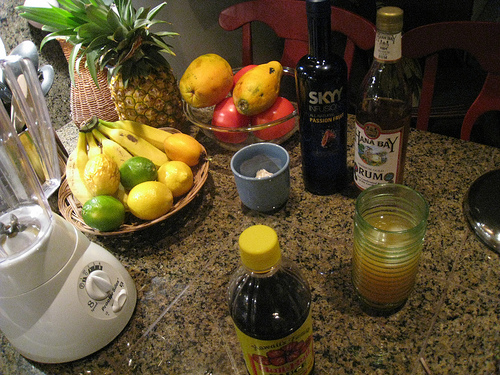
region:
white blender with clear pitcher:
[3, 28, 140, 367]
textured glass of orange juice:
[348, 171, 428, 329]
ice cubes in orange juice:
[368, 204, 419, 263]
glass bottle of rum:
[348, 0, 416, 200]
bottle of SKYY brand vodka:
[291, 2, 353, 197]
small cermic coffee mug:
[220, 140, 298, 220]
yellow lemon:
[118, 170, 179, 225]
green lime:
[78, 192, 128, 238]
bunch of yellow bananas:
[71, 99, 174, 181]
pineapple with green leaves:
[91, 5, 194, 132]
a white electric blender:
[0, 42, 142, 365]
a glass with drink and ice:
[343, 179, 434, 321]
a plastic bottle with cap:
[218, 224, 317, 372]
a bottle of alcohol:
[343, 0, 418, 203]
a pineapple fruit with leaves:
[35, 0, 186, 137]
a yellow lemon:
[124, 182, 174, 219]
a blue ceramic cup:
[225, 141, 297, 212]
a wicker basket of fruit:
[58, 114, 208, 236]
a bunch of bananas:
[59, 109, 175, 204]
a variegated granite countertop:
[0, 136, 497, 372]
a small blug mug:
[232, 141, 293, 201]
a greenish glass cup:
[352, 184, 422, 311]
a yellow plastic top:
[241, 226, 276, 268]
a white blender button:
[87, 270, 114, 296]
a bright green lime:
[80, 196, 123, 223]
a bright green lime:
[120, 156, 157, 181]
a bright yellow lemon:
[127, 182, 171, 214]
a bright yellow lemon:
[159, 160, 191, 192]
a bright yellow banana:
[92, 118, 173, 168]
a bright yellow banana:
[65, 120, 95, 203]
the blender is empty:
[11, 86, 185, 304]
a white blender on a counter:
[0, 45, 122, 365]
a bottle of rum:
[357, 7, 412, 189]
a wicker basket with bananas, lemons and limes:
[56, 123, 218, 223]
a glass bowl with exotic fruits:
[185, 60, 295, 142]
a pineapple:
[70, 5, 182, 125]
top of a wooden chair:
[213, 2, 374, 59]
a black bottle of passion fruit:
[291, 6, 353, 192]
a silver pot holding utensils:
[1, 39, 63, 176]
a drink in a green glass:
[348, 180, 431, 317]